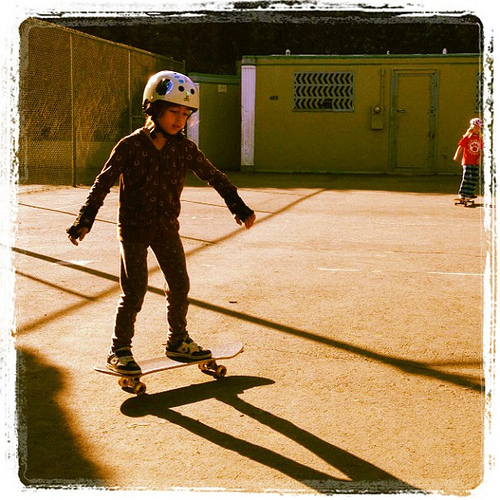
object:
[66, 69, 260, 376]
girl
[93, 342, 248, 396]
skateboard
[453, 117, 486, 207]
child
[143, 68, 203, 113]
helmet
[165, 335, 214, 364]
shoe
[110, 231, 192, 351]
sweat pants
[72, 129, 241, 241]
sweater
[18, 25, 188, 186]
fence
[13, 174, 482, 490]
asphalt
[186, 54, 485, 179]
building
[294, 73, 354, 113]
window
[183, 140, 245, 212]
left arm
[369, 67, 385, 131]
gas meter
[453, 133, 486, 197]
outfit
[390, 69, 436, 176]
entrance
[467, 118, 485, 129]
helmet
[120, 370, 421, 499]
shadow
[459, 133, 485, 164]
shirt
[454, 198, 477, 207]
skateboard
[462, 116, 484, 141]
hair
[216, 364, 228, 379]
wheel